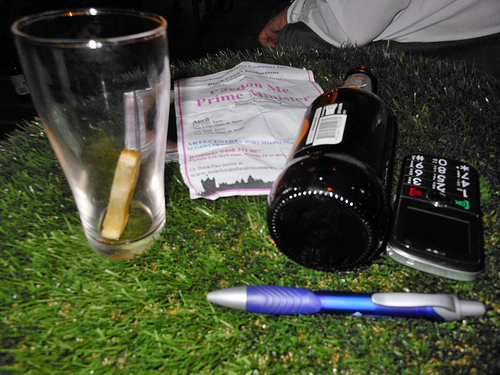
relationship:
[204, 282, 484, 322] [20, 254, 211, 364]
blue pen on grass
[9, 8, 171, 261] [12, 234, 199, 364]
glass on grass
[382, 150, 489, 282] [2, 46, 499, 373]
cell phone on grass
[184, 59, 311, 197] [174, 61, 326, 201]
prints on paper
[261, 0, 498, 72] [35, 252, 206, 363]
person in grass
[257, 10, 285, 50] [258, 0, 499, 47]
hand on person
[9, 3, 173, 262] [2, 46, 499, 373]
glass in grass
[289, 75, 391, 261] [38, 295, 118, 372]
bottle on grass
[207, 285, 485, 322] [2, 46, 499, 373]
blue pen on grass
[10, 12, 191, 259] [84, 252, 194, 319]
cup on grass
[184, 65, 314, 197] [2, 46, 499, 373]
paper on grass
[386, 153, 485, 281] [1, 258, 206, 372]
cell phone on grass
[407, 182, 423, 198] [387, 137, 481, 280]
red button on phone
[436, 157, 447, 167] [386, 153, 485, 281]
numbers on cell phone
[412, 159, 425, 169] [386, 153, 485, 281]
numbers on cell phone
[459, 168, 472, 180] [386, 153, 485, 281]
numbers on cell phone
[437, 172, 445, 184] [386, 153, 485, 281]
numbers on cell phone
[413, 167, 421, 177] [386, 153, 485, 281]
numbers on cell phone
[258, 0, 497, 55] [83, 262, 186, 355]
person on grass